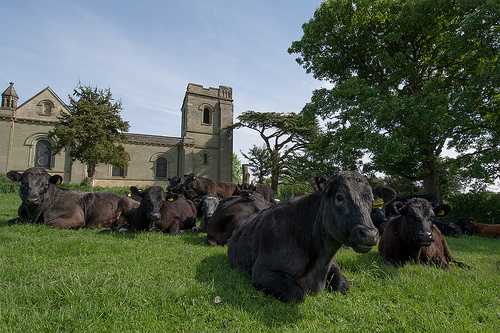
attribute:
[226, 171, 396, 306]
black cow — large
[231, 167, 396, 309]
cow — black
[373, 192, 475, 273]
cow — black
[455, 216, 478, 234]
cow — black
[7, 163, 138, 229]
cow — black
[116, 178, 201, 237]
cow — black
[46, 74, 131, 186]
small tree — single, green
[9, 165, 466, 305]
cows — black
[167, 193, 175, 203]
tag — yellow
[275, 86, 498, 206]
tree — big, tall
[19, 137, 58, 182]
door — black, large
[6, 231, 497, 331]
grass — green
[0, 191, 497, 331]
grass — green, short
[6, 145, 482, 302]
cattles — black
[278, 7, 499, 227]
tree — tall, green, healthy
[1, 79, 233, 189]
building — old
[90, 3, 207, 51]
sky — bright blue, white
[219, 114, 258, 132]
stem — thin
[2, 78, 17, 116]
temple — small, pointy